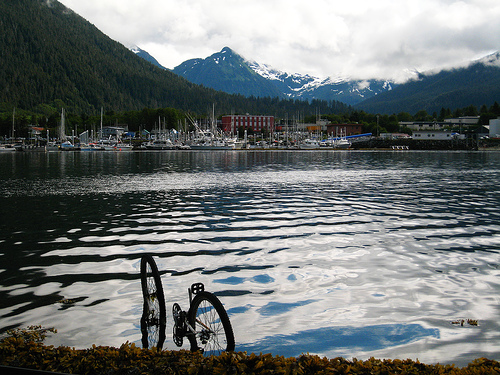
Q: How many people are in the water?
A: None.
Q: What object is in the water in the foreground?
A: A bicycle.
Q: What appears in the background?
A: Mountains and sky.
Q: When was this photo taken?
A: During the day.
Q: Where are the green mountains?
A: Behind the shoreline on the left.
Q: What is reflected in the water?
A: The sky.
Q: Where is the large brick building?
A: In the background along the shoreline.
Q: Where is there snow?
A: On the mountains in the background.